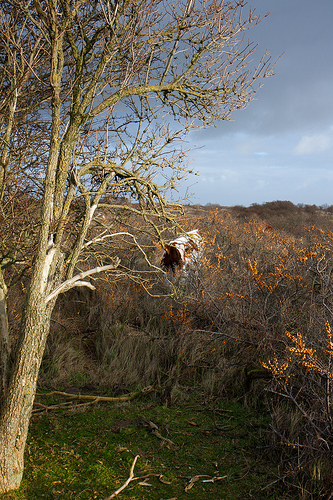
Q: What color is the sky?
A: Blue.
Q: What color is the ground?
A: Green.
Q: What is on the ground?
A: Stems.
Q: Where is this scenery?
A: In the field.